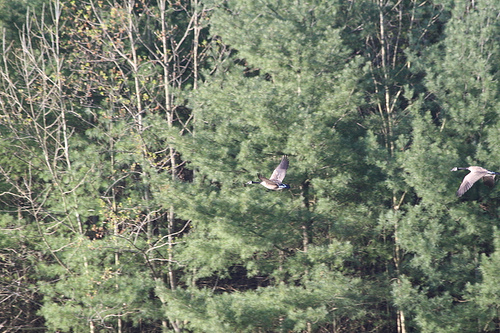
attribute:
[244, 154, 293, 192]
bird — airborne, in flight, soaring, flying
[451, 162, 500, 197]
bird — airborne, in flight, soaring, flying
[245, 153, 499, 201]
birds — facing each other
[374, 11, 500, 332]
tree — green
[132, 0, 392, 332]
tree — green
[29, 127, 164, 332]
tree — green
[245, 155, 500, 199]
ducks — flying, in sky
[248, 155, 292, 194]
duck — flying in air, in the sky, flying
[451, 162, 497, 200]
duck — flying in air, in the sky, flying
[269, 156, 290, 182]
wings — expanded, spread, outstretched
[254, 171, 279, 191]
wings — expanded, spread, outstretched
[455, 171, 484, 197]
wings — spread, expanded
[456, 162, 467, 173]
neck — long, outstretched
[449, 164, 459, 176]
face — black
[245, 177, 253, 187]
face — black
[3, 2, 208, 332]
tree — tall, leaveless, slim, leafless, slender, brown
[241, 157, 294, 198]
goose — flying, in mid flight, the leader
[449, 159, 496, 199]
goose — in mid flight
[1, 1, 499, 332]
forest — thick, lush, evergreen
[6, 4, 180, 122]
leaves — green, small, yellow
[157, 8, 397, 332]
pine tree — tall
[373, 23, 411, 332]
tree trunk — long